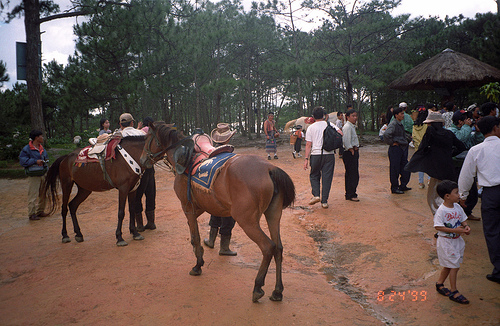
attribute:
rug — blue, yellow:
[186, 147, 237, 192]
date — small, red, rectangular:
[372, 288, 433, 303]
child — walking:
[431, 178, 471, 306]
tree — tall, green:
[334, 25, 359, 89]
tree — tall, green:
[249, 27, 264, 102]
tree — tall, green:
[193, 28, 227, 100]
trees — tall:
[73, 4, 409, 104]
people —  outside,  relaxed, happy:
[304, 106, 329, 207]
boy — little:
[431, 180, 471, 302]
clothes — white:
[433, 200, 466, 267]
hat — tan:
[422, 110, 445, 122]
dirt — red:
[1, 138, 492, 324]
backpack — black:
[324, 117, 344, 151]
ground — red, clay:
[20, 132, 487, 324]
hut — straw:
[379, 42, 495, 127]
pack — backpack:
[320, 120, 342, 154]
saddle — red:
[188, 130, 241, 157]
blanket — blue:
[175, 155, 241, 192]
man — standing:
[20, 129, 50, 221]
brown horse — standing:
[138, 120, 298, 307]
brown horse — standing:
[28, 127, 165, 248]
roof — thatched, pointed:
[397, 45, 497, 75]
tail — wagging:
[269, 166, 299, 213]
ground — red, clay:
[0, 143, 499, 323]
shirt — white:
[305, 119, 341, 155]